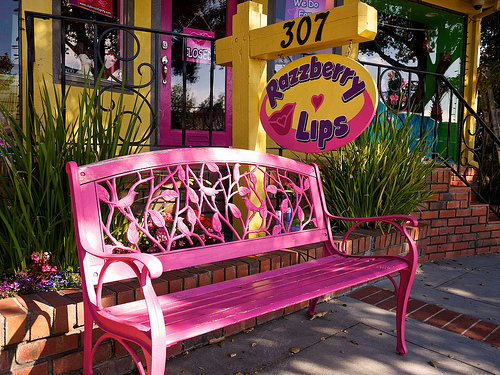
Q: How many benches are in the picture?
A: One.